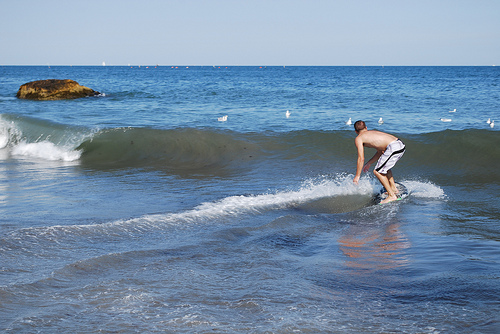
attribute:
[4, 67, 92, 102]
rock — brown, large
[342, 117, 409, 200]
surfer — male, surfing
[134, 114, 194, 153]
waves — incoming, white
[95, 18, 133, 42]
sky — blue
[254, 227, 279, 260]
water — blue, motionless, crashing, white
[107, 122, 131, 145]
wave — rolling, small, incoming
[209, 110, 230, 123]
bird — white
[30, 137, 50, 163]
foam — white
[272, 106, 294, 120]
birds — white